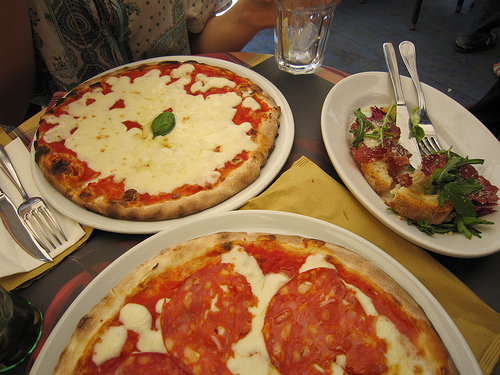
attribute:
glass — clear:
[274, 1, 340, 76]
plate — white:
[27, 209, 486, 374]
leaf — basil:
[149, 110, 178, 140]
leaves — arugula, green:
[434, 156, 495, 239]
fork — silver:
[0, 142, 69, 251]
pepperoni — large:
[160, 263, 388, 374]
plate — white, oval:
[319, 68, 499, 258]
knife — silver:
[379, 41, 423, 176]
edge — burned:
[34, 83, 101, 179]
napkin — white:
[1, 137, 88, 277]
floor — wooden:
[322, 4, 500, 105]